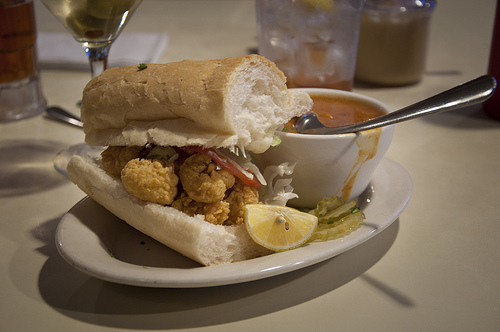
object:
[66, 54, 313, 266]
sandwich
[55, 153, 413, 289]
plate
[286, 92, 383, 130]
soup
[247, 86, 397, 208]
bowl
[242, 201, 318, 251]
lemon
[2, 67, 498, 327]
table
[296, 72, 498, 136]
spoon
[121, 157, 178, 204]
shrimp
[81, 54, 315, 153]
bread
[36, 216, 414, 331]
shadow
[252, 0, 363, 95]
cup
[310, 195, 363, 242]
pickle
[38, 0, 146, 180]
glass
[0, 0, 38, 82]
liquid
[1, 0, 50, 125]
cup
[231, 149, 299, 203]
lettuce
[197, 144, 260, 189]
tomato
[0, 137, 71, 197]
shadow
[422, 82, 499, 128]
shadow